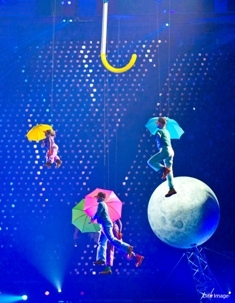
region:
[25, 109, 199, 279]
several people hanging from wires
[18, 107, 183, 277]
several people holding unbrellas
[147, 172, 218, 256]
a replica of the moon on a tower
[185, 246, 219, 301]
grey metal bars of the tower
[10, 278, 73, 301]
bright lights on the stage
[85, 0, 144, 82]
an umbrella hook in the air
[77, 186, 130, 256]
a man holding a pink umbrella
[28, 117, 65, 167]
a girl holding a yellow umbrella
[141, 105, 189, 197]
a man holding a blue umbrella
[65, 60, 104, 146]
lights on the back wall of the stage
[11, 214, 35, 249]
this is the background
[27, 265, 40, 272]
the background is blue in color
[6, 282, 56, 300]
these are some lights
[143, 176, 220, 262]
this is an object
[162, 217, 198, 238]
the object is white in color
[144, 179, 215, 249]
the object is round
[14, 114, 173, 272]
these are some people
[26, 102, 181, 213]
the people are holding umbrellas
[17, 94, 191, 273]
the people are above the ground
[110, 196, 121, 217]
the umbrella is pink in color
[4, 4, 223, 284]
people and umbrellas floating against blue background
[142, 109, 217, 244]
man standing on one foot on white planet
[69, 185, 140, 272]
people under separate umbrellas with curved back legs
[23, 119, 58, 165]
person with yellow umbrella holding red book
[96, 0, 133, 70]
silver and yellow curved handle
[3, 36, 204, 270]
stripe and panel of silvery dots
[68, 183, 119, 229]
open green and pink umbrellas with dark ribs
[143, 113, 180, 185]
person in blue outfit carrying blue umbrella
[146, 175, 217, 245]
light and dark side of spotted planet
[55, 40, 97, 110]
line of brighter dots against paler dots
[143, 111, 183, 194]
a person holding a blue umbrella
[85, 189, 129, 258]
a person holding a pink umbrella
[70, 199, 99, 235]
a green umbrella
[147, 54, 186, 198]
a person suspended by cables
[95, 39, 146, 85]
a white and yellow handle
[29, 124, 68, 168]
a person holding a yellow umbrella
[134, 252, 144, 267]
a person wearing a red boot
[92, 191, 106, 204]
a person wearing a baseball cap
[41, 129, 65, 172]
a person wearing a pink dress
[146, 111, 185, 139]
an umbrella that is open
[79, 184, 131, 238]
the umbrella is pink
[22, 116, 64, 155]
the umbrella is yellow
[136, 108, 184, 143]
the umbrella is blue